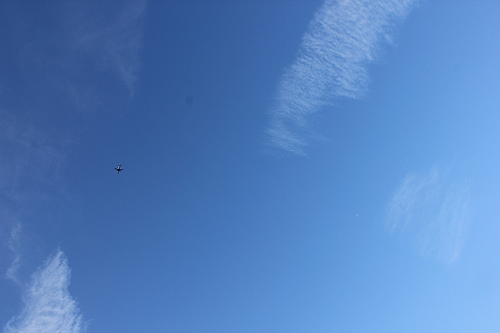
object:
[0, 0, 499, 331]
sky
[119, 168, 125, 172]
wing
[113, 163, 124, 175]
aircraft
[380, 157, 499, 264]
cloud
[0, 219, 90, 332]
cloud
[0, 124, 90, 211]
cloud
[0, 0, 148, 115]
cloud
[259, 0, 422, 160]
cloud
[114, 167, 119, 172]
wing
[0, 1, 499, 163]
forward